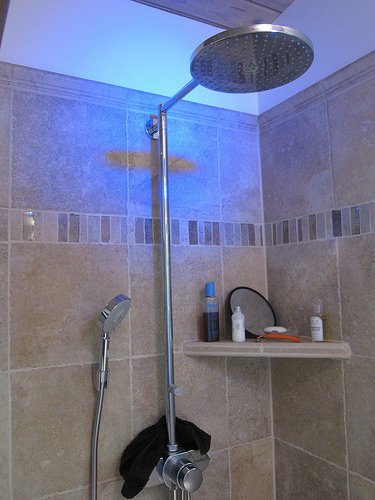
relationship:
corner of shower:
[223, 16, 292, 128] [5, 4, 364, 392]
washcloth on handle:
[89, 402, 227, 493] [140, 427, 207, 499]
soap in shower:
[222, 304, 254, 348] [5, 4, 364, 392]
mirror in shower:
[225, 282, 285, 342] [5, 4, 364, 392]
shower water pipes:
[5, 4, 364, 392] [147, 153, 195, 451]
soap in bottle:
[222, 304, 254, 348] [231, 306, 249, 343]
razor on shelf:
[251, 328, 316, 351] [196, 328, 365, 362]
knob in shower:
[155, 447, 218, 493] [5, 4, 364, 392]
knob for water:
[155, 447, 218, 493] [39, 16, 347, 493]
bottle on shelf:
[201, 282, 220, 347] [196, 328, 365, 362]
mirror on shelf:
[225, 282, 285, 342] [196, 328, 365, 362]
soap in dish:
[222, 304, 254, 348] [260, 330, 294, 342]